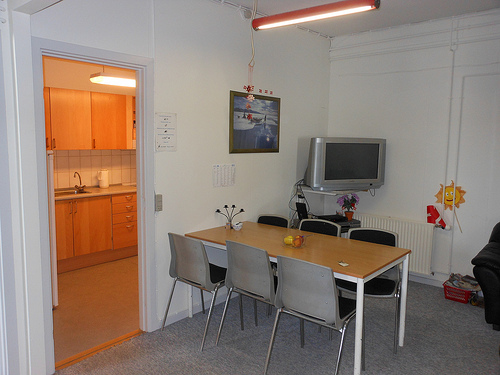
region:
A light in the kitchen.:
[89, 71, 139, 88]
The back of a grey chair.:
[276, 254, 336, 325]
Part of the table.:
[358, 244, 375, 267]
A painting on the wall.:
[228, 89, 280, 153]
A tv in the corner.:
[306, 133, 387, 193]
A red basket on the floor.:
[442, 284, 470, 304]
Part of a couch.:
[478, 262, 490, 283]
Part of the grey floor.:
[161, 344, 184, 370]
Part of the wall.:
[185, 164, 205, 196]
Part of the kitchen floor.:
[95, 285, 120, 319]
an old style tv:
[310, 138, 385, 187]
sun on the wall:
[437, 182, 464, 233]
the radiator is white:
[360, 205, 435, 276]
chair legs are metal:
[262, 310, 352, 373]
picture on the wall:
[230, 92, 281, 154]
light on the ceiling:
[250, 2, 377, 32]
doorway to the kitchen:
[32, 36, 154, 368]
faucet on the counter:
[73, 171, 82, 186]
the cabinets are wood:
[42, 85, 136, 150]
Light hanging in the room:
[251, 2, 379, 32]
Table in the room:
[186, 220, 411, 374]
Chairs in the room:
[158, 212, 403, 374]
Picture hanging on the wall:
[227, 89, 282, 154]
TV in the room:
[302, 134, 387, 193]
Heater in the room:
[348, 208, 439, 280]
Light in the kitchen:
[89, 65, 134, 87]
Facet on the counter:
[71, 171, 88, 193]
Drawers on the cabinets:
[109, 193, 139, 250]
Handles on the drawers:
[124, 193, 135, 230]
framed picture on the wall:
[227, 94, 281, 152]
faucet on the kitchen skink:
[75, 170, 82, 195]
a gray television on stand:
[309, 135, 385, 195]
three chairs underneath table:
[168, 243, 341, 350]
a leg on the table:
[355, 283, 364, 374]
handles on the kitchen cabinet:
[122, 193, 133, 239]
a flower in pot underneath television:
[340, 193, 358, 223]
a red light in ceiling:
[242, 3, 377, 26]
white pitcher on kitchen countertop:
[97, 168, 107, 188]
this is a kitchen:
[48, 62, 140, 334]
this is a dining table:
[171, 181, 416, 368]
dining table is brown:
[203, 194, 411, 302]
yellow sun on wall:
[436, 181, 488, 226]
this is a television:
[298, 120, 403, 201]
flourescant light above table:
[232, 0, 397, 48]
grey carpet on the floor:
[148, 334, 315, 373]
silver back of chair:
[270, 254, 357, 370]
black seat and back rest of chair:
[339, 218, 401, 307]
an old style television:
[306, 134, 384, 193]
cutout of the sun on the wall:
[435, 180, 462, 231]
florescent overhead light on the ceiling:
[252, 1, 376, 34]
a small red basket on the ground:
[441, 274, 479, 300]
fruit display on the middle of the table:
[283, 231, 308, 248]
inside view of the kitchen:
[40, 54, 143, 366]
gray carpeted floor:
[60, 279, 496, 373]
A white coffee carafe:
[96, 168, 107, 190]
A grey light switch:
[155, 194, 162, 209]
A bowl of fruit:
[282, 232, 308, 247]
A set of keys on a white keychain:
[337, 260, 349, 267]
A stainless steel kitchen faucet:
[72, 167, 87, 190]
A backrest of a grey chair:
[274, 255, 339, 326]